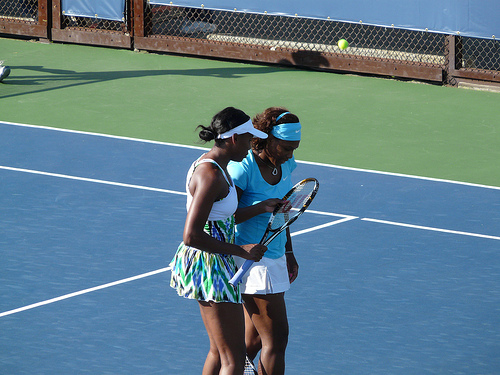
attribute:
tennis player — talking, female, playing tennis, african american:
[169, 107, 253, 373]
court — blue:
[1, 39, 499, 374]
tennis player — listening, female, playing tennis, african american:
[227, 107, 300, 374]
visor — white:
[217, 117, 268, 139]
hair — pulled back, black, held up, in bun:
[197, 106, 251, 146]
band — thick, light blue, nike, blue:
[273, 123, 301, 140]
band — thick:
[275, 110, 293, 120]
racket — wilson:
[227, 176, 319, 285]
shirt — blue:
[225, 150, 297, 259]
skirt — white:
[230, 252, 290, 296]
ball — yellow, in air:
[338, 39, 349, 50]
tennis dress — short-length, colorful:
[169, 151, 245, 302]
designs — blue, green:
[169, 215, 241, 304]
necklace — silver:
[254, 152, 282, 176]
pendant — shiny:
[272, 167, 279, 175]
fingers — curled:
[279, 198, 292, 213]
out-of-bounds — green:
[0, 37, 499, 185]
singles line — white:
[0, 217, 357, 319]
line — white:
[0, 120, 499, 191]